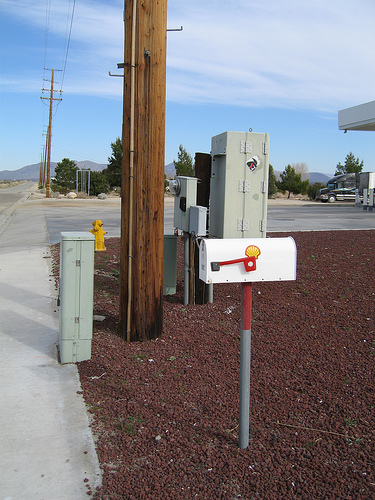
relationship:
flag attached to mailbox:
[211, 252, 258, 273] [195, 235, 299, 305]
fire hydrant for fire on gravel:
[89, 220, 106, 252] [113, 223, 372, 324]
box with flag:
[199, 236, 297, 285] [241, 241, 264, 312]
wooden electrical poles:
[122, 203, 162, 372] [39, 66, 65, 198]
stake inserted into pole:
[195, 230, 274, 328] [240, 277, 252, 451]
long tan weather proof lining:
[119, 126, 137, 342] [124, 0, 137, 342]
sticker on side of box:
[243, 150, 269, 176] [197, 233, 296, 295]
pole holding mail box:
[178, 281, 271, 481] [199, 225, 304, 294]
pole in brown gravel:
[119, 0, 167, 343] [42, 230, 373, 496]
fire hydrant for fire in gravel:
[89, 220, 106, 252] [0, 306, 160, 500]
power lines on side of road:
[35, 6, 67, 172] [28, 338, 83, 498]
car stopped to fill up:
[318, 186, 362, 203] [334, 257, 351, 299]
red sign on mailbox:
[210, 248, 261, 272] [193, 235, 301, 285]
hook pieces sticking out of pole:
[166, 22, 184, 33] [119, 2, 166, 333]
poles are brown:
[35, 66, 68, 193] [124, 249, 138, 312]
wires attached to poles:
[40, 0, 93, 140] [45, 46, 100, 93]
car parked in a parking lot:
[318, 171, 375, 204] [303, 149, 352, 217]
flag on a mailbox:
[211, 252, 258, 273] [195, 228, 300, 289]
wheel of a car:
[326, 194, 338, 204] [315, 186, 356, 205]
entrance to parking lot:
[5, 199, 48, 254] [277, 196, 373, 228]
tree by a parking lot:
[276, 166, 302, 200] [29, 195, 364, 244]